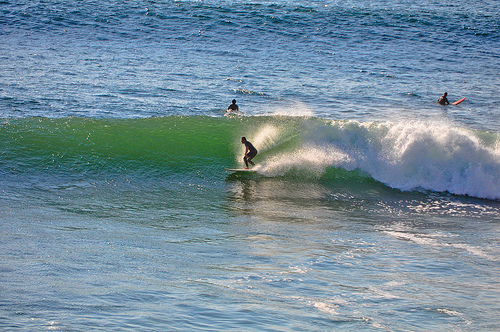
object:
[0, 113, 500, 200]
wave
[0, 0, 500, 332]
ground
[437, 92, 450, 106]
man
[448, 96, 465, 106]
surfboard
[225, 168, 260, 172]
surfboard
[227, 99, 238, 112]
man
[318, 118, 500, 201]
wave crest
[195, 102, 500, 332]
foam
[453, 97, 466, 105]
board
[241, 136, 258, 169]
man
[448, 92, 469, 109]
surfboard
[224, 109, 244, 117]
surfboard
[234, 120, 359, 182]
spray